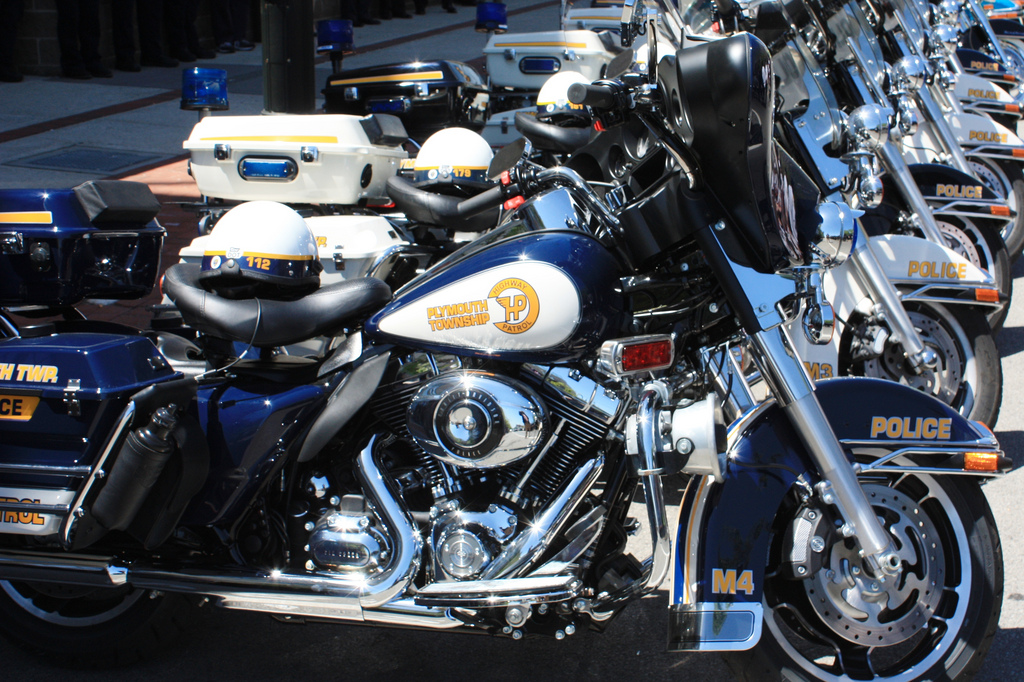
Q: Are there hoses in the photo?
A: No, there are no hoses.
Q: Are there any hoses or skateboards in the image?
A: No, there are no hoses or skateboards.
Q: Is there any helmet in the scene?
A: Yes, there is a helmet.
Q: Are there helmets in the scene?
A: Yes, there is a helmet.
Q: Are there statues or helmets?
A: Yes, there is a helmet.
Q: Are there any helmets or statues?
A: Yes, there is a helmet.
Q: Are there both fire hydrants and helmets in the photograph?
A: No, there is a helmet but no fire hydrants.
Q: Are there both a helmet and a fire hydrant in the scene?
A: No, there is a helmet but no fire hydrants.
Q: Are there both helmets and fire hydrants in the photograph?
A: No, there is a helmet but no fire hydrants.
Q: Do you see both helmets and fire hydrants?
A: No, there is a helmet but no fire hydrants.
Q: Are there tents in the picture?
A: No, there are no tents.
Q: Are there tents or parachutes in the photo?
A: No, there are no tents or parachutes.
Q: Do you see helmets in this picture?
A: Yes, there is a helmet.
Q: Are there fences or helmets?
A: Yes, there is a helmet.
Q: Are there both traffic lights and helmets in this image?
A: No, there is a helmet but no traffic lights.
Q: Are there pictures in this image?
A: No, there are no pictures.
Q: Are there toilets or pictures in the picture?
A: No, there are no pictures or toilets.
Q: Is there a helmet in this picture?
A: Yes, there is a helmet.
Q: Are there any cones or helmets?
A: Yes, there is a helmet.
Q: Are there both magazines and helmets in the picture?
A: No, there is a helmet but no magazines.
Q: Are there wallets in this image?
A: No, there are no wallets.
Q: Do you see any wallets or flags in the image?
A: No, there are no wallets or flags.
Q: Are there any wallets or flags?
A: No, there are no wallets or flags.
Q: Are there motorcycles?
A: Yes, there is a motorcycle.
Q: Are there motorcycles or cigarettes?
A: Yes, there is a motorcycle.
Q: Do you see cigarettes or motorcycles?
A: Yes, there is a motorcycle.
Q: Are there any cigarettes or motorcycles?
A: Yes, there is a motorcycle.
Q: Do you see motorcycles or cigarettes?
A: Yes, there is a motorcycle.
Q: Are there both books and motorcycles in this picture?
A: No, there is a motorcycle but no books.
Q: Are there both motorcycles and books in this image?
A: No, there is a motorcycle but no books.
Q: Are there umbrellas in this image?
A: No, there are no umbrellas.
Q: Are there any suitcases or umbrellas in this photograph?
A: No, there are no umbrellas or suitcases.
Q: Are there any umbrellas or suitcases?
A: No, there are no umbrellas or suitcases.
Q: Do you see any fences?
A: No, there are no fences.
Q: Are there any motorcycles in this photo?
A: Yes, there is a motorcycle.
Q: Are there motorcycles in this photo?
A: Yes, there is a motorcycle.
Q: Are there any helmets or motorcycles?
A: Yes, there is a motorcycle.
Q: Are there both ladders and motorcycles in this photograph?
A: No, there is a motorcycle but no ladders.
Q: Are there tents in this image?
A: No, there are no tents.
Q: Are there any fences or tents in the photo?
A: No, there are no tents or fences.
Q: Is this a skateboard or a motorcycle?
A: This is a motorcycle.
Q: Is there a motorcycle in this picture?
A: Yes, there is a motorcycle.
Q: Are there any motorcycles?
A: Yes, there is a motorcycle.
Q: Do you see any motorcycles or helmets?
A: Yes, there is a motorcycle.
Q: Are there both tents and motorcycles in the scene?
A: No, there is a motorcycle but no tents.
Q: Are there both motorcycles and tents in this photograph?
A: No, there is a motorcycle but no tents.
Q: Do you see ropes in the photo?
A: No, there are no ropes.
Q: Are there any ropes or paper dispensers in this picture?
A: No, there are no ropes or paper dispensers.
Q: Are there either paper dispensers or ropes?
A: No, there are no ropes or paper dispensers.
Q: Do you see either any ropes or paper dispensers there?
A: No, there are no ropes or paper dispensers.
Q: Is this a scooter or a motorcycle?
A: This is a motorcycle.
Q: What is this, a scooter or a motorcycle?
A: This is a motorcycle.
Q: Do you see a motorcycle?
A: Yes, there is a motorcycle.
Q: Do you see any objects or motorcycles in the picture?
A: Yes, there is a motorcycle.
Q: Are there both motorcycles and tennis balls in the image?
A: No, there is a motorcycle but no tennis balls.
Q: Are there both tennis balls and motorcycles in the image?
A: No, there is a motorcycle but no tennis balls.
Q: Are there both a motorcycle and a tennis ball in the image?
A: No, there is a motorcycle but no tennis balls.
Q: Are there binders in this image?
A: No, there are no binders.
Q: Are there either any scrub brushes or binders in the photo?
A: No, there are no binders or scrub brushes.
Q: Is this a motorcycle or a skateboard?
A: This is a motorcycle.